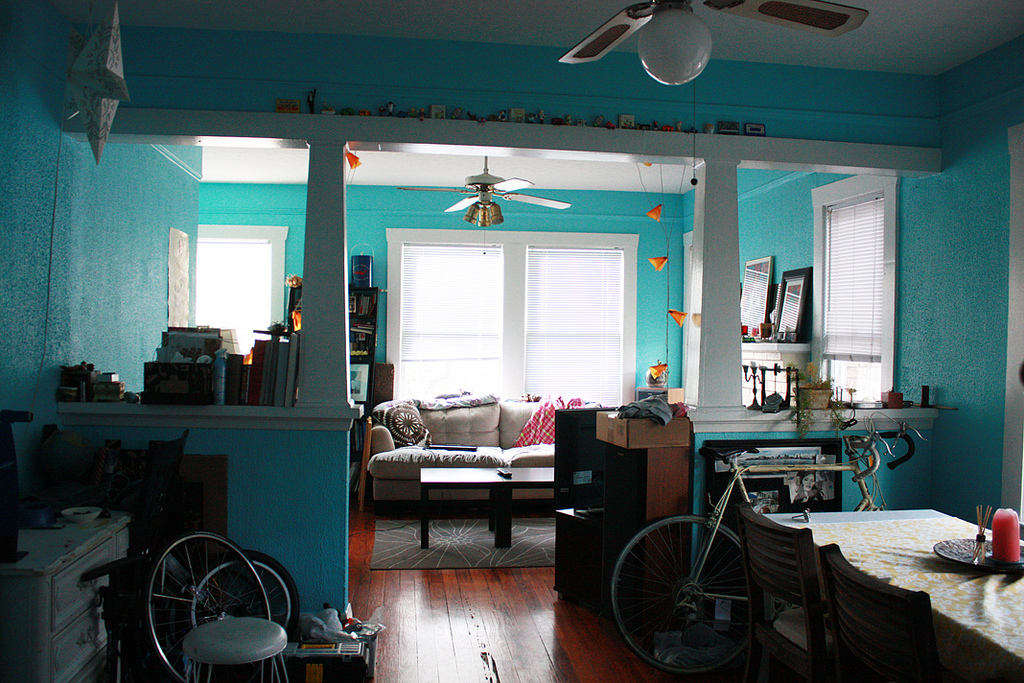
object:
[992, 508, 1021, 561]
candle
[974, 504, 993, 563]
diffuser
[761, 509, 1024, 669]
table